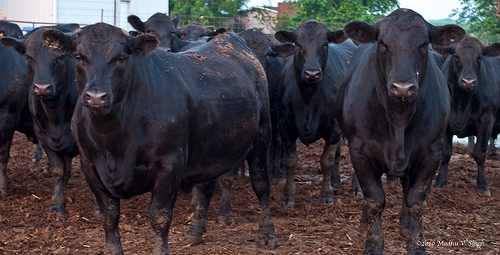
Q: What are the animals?
A: Cows.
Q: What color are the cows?
A: Black.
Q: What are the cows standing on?
A: Mulch.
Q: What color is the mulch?
A: Red.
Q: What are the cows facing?
A: The camera.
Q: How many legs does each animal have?
A: Four.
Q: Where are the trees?
A: Behind the cows.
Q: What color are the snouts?
A: Pink.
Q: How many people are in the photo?
A: None.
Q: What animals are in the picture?
A: Cows.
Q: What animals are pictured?
A: Cows.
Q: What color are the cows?
A: Black.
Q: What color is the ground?
A: Brown.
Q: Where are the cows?
A: In a field.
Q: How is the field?
A: Muddy.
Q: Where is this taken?
A: At a farm.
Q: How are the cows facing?
A: Forward.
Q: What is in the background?
A: Trees.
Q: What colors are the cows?
A: Black.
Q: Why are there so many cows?
A: It is a farm.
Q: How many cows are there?
A: 9.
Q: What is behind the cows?
A: Trees.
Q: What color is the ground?
A: Brown.